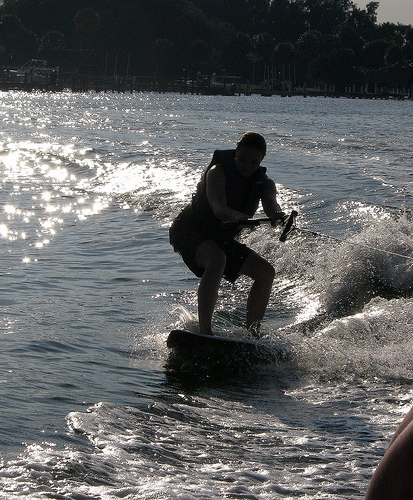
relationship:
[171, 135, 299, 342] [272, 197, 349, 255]
watersurfer being pulled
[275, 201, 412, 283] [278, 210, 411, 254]
ski tow line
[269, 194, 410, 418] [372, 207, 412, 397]
wake from engine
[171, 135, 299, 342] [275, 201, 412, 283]
watersurfer pulled by boat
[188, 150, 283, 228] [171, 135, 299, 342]
vest on surfer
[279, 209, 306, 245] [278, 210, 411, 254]
handle of line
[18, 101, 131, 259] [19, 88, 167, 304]
sunlight on water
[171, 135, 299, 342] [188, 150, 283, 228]
man wearing lifejacket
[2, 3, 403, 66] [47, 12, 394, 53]
trees in distance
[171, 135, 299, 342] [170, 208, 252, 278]
woman wearing shorts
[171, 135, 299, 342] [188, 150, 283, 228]
woman wearing vest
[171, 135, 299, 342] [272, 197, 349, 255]
woman holding pole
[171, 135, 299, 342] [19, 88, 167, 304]
woman on water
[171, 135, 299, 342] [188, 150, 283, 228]
woman in lifejacket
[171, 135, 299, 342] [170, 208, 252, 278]
woman wearing trunks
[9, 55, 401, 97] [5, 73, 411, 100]
boats docked at dock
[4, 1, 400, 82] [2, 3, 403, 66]
trees at shoreline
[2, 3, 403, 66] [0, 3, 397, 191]
trees in background